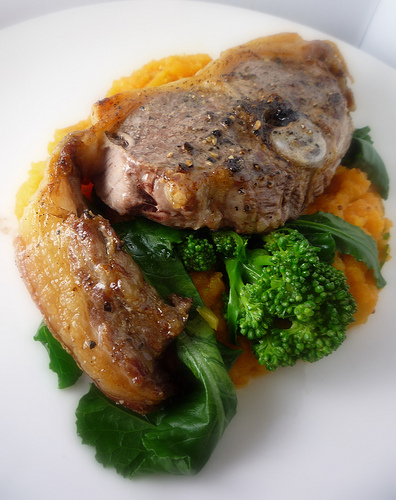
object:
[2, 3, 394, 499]
plate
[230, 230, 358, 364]
broccoli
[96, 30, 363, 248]
steak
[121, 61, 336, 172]
condiment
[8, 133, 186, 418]
bacon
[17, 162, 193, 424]
steak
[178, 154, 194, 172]
peppercorns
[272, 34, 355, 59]
fat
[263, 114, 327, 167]
bone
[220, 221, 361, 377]
piece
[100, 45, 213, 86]
sweet potato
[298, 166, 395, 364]
sweet potato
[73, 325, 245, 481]
lettuce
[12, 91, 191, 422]
fat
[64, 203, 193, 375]
pepper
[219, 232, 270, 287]
stem